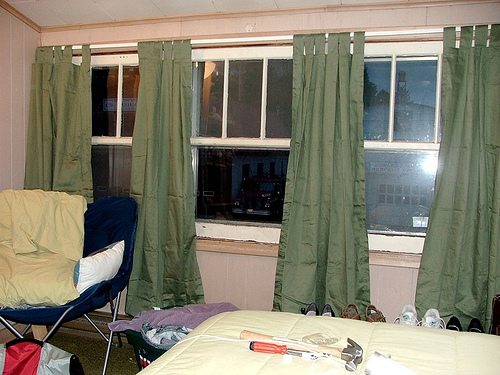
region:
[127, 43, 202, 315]
A green curtain closed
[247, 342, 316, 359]
A screwdriver on a bed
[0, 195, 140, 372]
A blue folding chair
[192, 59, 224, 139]
A glass window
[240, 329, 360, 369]
A wooden hammer on a bed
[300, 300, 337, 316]
A pair of black and white shoes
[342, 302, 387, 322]
A pair of brown shoes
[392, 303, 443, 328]
A pair of all white shoes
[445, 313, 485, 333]
A pair of plain black shoes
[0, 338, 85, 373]
A red and silver bag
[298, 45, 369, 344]
this is a curtain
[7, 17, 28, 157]
this is a wall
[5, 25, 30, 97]
the wall is brown in color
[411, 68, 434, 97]
this is the sky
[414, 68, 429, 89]
the sky is blue in color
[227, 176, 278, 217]
this is a car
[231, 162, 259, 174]
this is a wall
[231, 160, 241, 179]
the wall is white in color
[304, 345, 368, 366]
this is a hammer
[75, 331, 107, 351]
this is the floor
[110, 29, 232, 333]
the curtain is drawn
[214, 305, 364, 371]
a hammer on the bed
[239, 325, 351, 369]
a hammer on the bed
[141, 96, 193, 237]
the curtains are green in color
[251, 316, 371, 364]
the hammer is on the bed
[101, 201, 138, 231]
the seat is blue in color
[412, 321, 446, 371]
the bed sheett is lime white in color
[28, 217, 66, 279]
the pillow is faded yellow in color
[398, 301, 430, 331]
the shoes are white in color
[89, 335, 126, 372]
the floor is carpete in green color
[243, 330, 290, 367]
the hand of chissel is red in color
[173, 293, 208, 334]
the clothes are purple in color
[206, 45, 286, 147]
the window panes are white in color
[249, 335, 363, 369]
hammer with a red handle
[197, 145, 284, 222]
open middle window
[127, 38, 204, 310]
green curtain panel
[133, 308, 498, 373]
white comforter on a bed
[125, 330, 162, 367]
part of green laundry basket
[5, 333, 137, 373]
ugly green carpeting section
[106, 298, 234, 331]
light purple towel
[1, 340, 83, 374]
pink and gray duffel bag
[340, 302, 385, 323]
pair of brown sandals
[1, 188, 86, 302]
white blanket on blue chairs